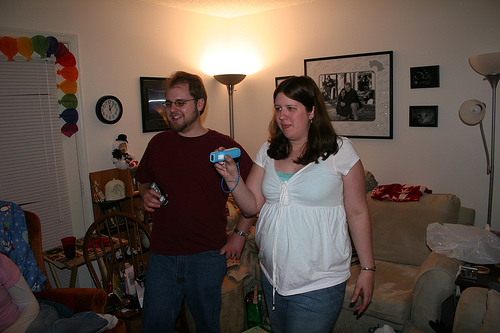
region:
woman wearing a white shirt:
[239, 69, 341, 331]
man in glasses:
[136, 51, 246, 331]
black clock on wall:
[91, 86, 134, 140]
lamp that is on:
[212, 56, 264, 156]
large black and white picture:
[311, 51, 395, 150]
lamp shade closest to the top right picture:
[465, 44, 499, 76]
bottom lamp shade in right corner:
[456, 91, 496, 148]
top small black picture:
[401, 61, 448, 93]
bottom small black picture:
[408, 105, 448, 135]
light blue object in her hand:
[212, 145, 244, 167]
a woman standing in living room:
[205, 72, 375, 331]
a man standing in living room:
[135, 69, 258, 331]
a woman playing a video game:
[207, 74, 375, 331]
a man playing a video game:
[134, 67, 258, 331]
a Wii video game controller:
[208, 145, 241, 194]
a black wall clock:
[93, 95, 123, 125]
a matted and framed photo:
[297, 50, 393, 142]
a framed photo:
[405, 103, 438, 128]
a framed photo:
[406, 64, 441, 89]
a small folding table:
[40, 231, 130, 301]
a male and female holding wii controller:
[97, 49, 376, 326]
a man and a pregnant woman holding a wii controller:
[119, 57, 379, 322]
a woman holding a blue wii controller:
[208, 72, 378, 332]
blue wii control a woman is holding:
[206, 143, 246, 166]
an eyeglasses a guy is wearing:
[161, 96, 191, 109]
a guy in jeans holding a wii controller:
[128, 69, 240, 331]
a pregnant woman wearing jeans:
[208, 73, 381, 332]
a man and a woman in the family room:
[123, 60, 374, 326]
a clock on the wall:
[92, 90, 127, 127]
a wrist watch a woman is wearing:
[357, 263, 377, 272]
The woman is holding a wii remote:
[210, 56, 340, 316]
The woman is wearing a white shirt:
[251, 136, 386, 291]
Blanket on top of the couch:
[370, 165, 461, 227]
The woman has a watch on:
[352, 255, 384, 271]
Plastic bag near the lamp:
[426, 207, 496, 279]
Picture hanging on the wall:
[306, 49, 421, 148]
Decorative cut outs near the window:
[10, 28, 108, 143]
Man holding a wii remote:
[125, 135, 180, 239]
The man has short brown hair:
[165, 63, 213, 149]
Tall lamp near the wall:
[457, 30, 499, 155]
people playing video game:
[118, 58, 346, 330]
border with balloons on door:
[6, 37, 82, 137]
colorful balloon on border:
[64, 123, 78, 141]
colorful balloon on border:
[59, 110, 76, 124]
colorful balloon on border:
[60, 98, 75, 109]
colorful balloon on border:
[56, 83, 78, 92]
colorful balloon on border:
[60, 64, 77, 80]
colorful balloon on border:
[61, 70, 76, 82]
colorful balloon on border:
[57, 54, 69, 67]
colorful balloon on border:
[34, 41, 44, 60]